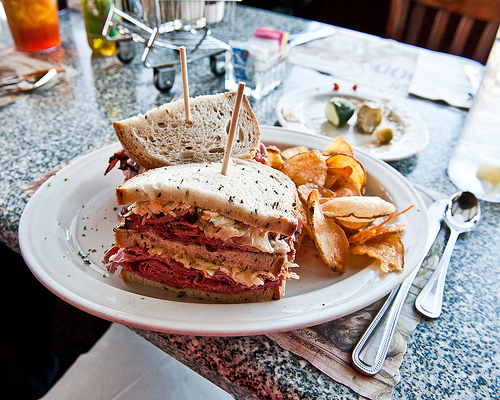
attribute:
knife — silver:
[348, 198, 451, 375]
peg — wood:
[219, 81, 246, 173]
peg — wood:
[176, 46, 192, 123]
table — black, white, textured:
[0, 4, 499, 399]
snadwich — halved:
[103, 154, 308, 303]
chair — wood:
[385, 0, 499, 60]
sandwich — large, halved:
[101, 156, 307, 304]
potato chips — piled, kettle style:
[266, 136, 408, 277]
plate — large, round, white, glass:
[18, 125, 433, 338]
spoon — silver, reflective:
[413, 189, 482, 319]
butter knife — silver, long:
[350, 197, 450, 377]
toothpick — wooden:
[178, 45, 194, 125]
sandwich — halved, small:
[106, 90, 262, 180]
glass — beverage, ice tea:
[2, 0, 63, 54]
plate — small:
[276, 85, 430, 162]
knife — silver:
[367, 202, 453, 392]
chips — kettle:
[285, 129, 391, 269]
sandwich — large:
[111, 86, 303, 303]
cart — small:
[104, 7, 231, 94]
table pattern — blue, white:
[0, 3, 497, 397]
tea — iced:
[0, 0, 60, 53]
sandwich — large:
[111, 157, 301, 297]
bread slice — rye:
[113, 159, 303, 239]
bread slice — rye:
[111, 222, 289, 275]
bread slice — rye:
[118, 265, 284, 305]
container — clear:
[218, 33, 293, 99]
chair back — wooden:
[385, 2, 499, 66]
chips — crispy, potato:
[269, 138, 418, 279]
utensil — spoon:
[417, 184, 485, 328]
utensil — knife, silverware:
[351, 194, 451, 375]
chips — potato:
[257, 133, 413, 282]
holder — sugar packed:
[219, 24, 292, 95]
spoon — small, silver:
[415, 182, 484, 320]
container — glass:
[218, 31, 291, 94]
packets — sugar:
[233, 23, 287, 67]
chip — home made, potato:
[307, 196, 353, 274]